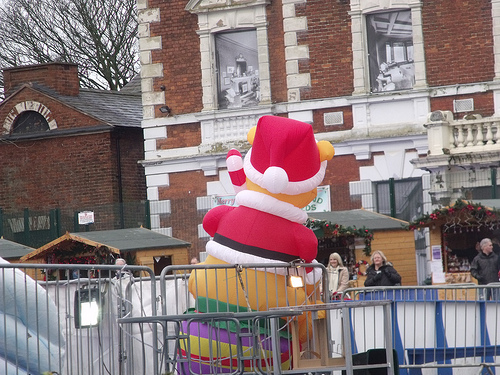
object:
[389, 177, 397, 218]
bars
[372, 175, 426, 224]
window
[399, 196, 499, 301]
booth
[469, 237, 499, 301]
man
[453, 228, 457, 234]
lights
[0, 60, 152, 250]
building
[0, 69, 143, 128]
roof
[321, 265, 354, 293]
tan jacket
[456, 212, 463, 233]
holly lights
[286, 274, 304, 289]
outdoor light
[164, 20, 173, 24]
bricks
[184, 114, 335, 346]
bear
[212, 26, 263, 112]
window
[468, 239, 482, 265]
vendor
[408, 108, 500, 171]
balcony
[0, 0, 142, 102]
tree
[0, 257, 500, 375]
fencing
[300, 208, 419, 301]
shed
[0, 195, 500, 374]
street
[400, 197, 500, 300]
store front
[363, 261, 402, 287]
jacket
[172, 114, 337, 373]
christmas display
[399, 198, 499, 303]
shed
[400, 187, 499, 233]
christmas decorations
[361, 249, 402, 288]
woman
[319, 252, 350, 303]
woman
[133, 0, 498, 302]
building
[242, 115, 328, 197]
hat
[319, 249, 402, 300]
couple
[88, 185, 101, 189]
bricks